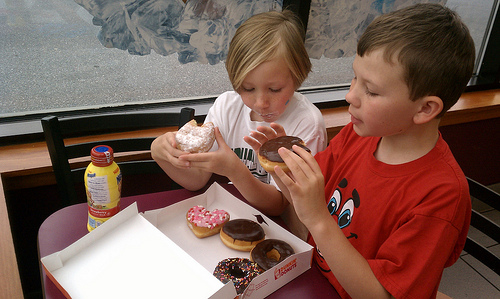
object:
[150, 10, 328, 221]
kid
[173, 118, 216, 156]
donut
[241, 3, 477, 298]
boy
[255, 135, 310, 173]
donut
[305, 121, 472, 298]
shirt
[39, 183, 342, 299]
table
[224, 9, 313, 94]
hair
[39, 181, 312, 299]
donut box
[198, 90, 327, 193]
shirt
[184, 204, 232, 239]
donuts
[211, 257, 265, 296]
donut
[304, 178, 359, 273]
smiley face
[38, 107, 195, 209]
chair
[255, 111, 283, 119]
sugar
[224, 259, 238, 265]
sprinkles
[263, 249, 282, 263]
hole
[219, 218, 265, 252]
donut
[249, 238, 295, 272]
donut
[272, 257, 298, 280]
label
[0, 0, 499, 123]
window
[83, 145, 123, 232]
bottle